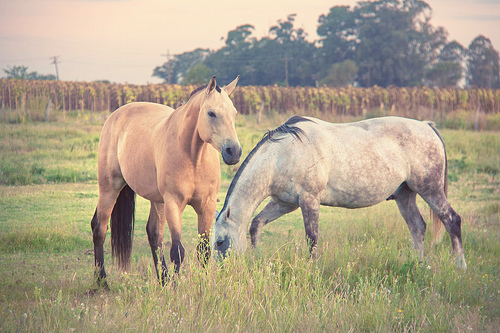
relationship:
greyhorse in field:
[214, 115, 467, 279] [5, 73, 500, 330]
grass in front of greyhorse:
[348, 240, 439, 295] [214, 115, 467, 279]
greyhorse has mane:
[214, 115, 467, 279] [218, 118, 307, 161]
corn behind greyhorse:
[0, 82, 497, 110] [214, 115, 467, 279]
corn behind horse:
[0, 82, 497, 110] [88, 72, 243, 294]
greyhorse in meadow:
[214, 115, 467, 279] [0, 80, 492, 332]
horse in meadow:
[89, 74, 243, 297] [0, 80, 492, 332]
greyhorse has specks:
[214, 115, 467, 279] [334, 147, 371, 194]